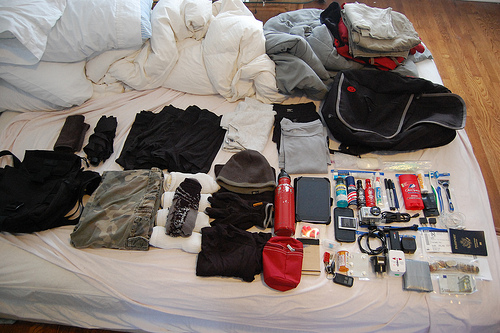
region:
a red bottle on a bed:
[273, 165, 294, 238]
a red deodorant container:
[396, 170, 428, 217]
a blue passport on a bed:
[446, 226, 488, 259]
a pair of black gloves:
[205, 189, 278, 232]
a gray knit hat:
[210, 141, 278, 190]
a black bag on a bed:
[319, 58, 477, 155]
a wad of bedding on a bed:
[0, 0, 266, 116]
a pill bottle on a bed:
[335, 244, 352, 269]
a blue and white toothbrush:
[431, 168, 447, 216]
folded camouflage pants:
[69, 162, 165, 257]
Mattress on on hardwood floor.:
[0, 12, 490, 329]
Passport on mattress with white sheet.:
[1, 20, 496, 325]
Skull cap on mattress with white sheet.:
[0, 35, 495, 326]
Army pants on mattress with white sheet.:
[0, 32, 496, 327]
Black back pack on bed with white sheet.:
[2, 32, 498, 329]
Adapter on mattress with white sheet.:
[1, 32, 498, 332]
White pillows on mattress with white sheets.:
[0, 5, 499, 331]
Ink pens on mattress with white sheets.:
[0, 36, 496, 329]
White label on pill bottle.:
[334, 245, 351, 272]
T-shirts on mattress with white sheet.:
[1, 0, 498, 329]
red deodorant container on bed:
[396, 170, 422, 211]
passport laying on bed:
[449, 226, 489, 256]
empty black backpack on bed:
[320, 63, 467, 146]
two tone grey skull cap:
[214, 143, 280, 194]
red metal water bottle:
[272, 165, 294, 235]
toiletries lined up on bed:
[331, 160, 460, 216]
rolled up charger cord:
[357, 225, 388, 275]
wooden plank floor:
[462, 13, 497, 115]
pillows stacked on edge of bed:
[4, 0, 154, 104]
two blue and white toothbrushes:
[426, 168, 446, 211]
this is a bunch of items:
[16, 9, 479, 290]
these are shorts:
[92, 171, 187, 271]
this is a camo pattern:
[98, 182, 171, 257]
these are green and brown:
[88, 171, 171, 260]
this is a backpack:
[316, 77, 472, 132]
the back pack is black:
[312, 79, 467, 116]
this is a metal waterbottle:
[262, 157, 300, 216]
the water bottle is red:
[268, 175, 300, 223]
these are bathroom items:
[336, 171, 433, 222]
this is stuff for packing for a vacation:
[19, 19, 426, 321]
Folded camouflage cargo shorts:
[69, 167, 165, 253]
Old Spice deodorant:
[397, 171, 424, 211]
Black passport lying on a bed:
[445, 224, 488, 258]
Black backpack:
[322, 65, 464, 155]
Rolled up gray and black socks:
[165, 173, 202, 240]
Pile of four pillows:
[0, 0, 155, 107]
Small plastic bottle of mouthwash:
[333, 176, 348, 209]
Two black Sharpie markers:
[380, 175, 399, 212]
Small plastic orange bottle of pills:
[333, 245, 352, 272]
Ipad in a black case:
[292, 174, 332, 224]